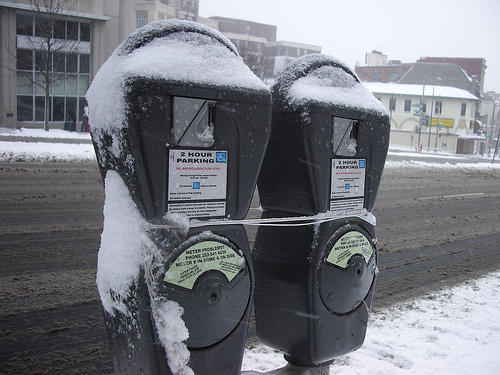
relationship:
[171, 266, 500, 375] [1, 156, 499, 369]
snow on road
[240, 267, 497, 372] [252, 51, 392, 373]
snow on meter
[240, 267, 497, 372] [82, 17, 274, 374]
snow on meter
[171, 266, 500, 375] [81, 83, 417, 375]
snow on machines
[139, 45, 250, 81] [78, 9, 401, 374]
snow on meters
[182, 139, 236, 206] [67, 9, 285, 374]
white sticker on meter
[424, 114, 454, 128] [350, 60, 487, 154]
sign on building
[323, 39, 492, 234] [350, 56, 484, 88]
building has roof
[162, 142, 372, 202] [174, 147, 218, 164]
words says 2-hour parking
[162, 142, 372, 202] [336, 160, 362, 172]
words says 2-hour parking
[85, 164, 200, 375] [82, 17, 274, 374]
snow on meter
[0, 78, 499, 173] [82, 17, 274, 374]
snow on meter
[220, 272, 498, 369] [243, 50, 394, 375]
snow on meter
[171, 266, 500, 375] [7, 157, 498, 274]
snow on road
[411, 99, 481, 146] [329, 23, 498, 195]
banner on building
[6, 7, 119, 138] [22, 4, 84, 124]
windows behind tree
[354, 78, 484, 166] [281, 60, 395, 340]
building building meter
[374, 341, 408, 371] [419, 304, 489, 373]
footprint in snow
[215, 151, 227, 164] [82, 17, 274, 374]
handicap sign on meter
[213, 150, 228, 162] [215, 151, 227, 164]
handicap sign on handicap sign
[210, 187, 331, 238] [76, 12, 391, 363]
strings around parking meters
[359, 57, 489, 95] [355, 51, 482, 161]
roof of building